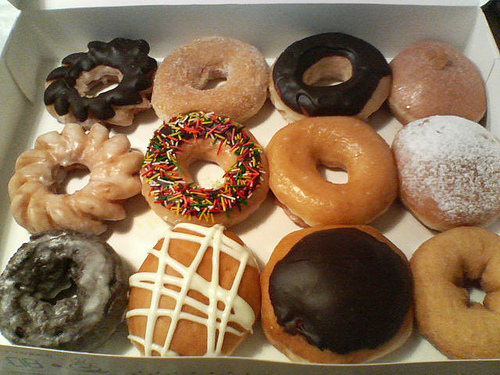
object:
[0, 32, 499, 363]
food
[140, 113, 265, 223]
item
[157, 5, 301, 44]
plate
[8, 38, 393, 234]
items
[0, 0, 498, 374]
box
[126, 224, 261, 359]
lines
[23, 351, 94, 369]
symbols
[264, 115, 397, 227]
donut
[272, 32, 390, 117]
donut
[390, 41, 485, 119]
donut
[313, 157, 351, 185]
hole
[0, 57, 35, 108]
seam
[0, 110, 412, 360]
donuts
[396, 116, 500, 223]
donut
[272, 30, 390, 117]
chocolate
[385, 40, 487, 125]
pastry